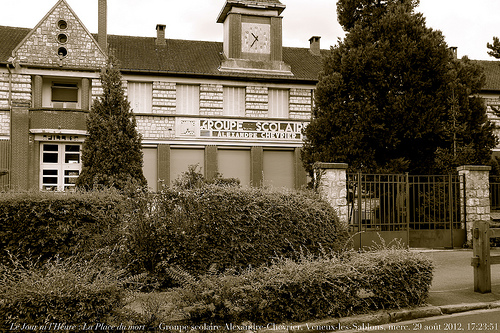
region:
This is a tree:
[326, 2, 463, 214]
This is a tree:
[81, 47, 164, 210]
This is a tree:
[451, 40, 499, 160]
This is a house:
[11, 0, 498, 275]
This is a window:
[39, 77, 86, 109]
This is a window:
[123, 80, 159, 111]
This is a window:
[173, 81, 204, 113]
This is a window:
[221, 85, 251, 117]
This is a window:
[266, 85, 293, 120]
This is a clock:
[241, 18, 273, 54]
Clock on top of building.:
[233, 16, 283, 73]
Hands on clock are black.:
[246, 20, 271, 65]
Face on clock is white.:
[240, 22, 287, 82]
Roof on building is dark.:
[126, 30, 200, 80]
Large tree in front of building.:
[354, 23, 437, 152]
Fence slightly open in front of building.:
[365, 168, 468, 238]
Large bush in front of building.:
[140, 198, 317, 256]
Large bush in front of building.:
[26, 189, 92, 263]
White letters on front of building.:
[192, 116, 307, 149]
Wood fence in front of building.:
[461, 221, 496, 268]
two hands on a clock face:
[238, 20, 270, 60]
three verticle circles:
[57, 13, 68, 68]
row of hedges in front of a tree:
[11, 197, 343, 275]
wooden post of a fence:
[472, 214, 497, 282]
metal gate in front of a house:
[351, 165, 462, 242]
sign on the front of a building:
[182, 115, 312, 145]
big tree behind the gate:
[315, 15, 479, 230]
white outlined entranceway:
[35, 135, 83, 203]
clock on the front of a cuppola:
[218, 11, 288, 78]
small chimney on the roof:
[147, 23, 171, 55]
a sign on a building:
[195, 109, 307, 144]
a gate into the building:
[344, 159, 471, 244]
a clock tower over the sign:
[221, 0, 291, 78]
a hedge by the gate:
[0, 188, 341, 265]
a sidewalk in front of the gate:
[14, 244, 499, 327]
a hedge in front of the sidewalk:
[3, 247, 428, 332]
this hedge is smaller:
[0, 244, 437, 316]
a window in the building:
[28, 131, 95, 197]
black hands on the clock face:
[242, 22, 269, 52]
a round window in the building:
[54, 47, 74, 62]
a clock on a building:
[230, 14, 290, 59]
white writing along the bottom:
[7, 317, 498, 331]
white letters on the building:
[189, 115, 306, 144]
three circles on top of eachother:
[47, 11, 71, 66]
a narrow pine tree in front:
[69, 47, 158, 205]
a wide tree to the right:
[285, 10, 499, 214]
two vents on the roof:
[132, 5, 356, 68]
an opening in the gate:
[332, 161, 464, 255]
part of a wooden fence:
[446, 212, 498, 308]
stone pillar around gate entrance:
[308, 157, 357, 258]